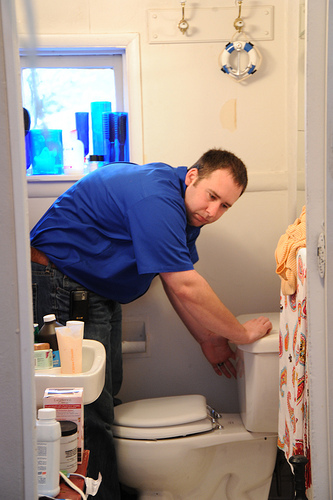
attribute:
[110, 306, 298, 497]
toilet — white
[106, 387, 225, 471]
seat — white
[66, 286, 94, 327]
phone — hanging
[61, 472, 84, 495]
cord — white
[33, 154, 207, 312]
shirt — blue, bright blue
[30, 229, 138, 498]
jeans — blue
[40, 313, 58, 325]
cap — white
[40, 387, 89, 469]
box — pink, unopened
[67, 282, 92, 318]
case — black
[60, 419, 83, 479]
bottle — white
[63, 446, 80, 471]
label — black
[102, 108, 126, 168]
hairbrushes — blue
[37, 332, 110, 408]
pedestal sink — white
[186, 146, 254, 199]
hair — brown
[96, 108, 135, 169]
jar — blue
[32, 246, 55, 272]
belt — brown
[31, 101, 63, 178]
life preserver — blue, white